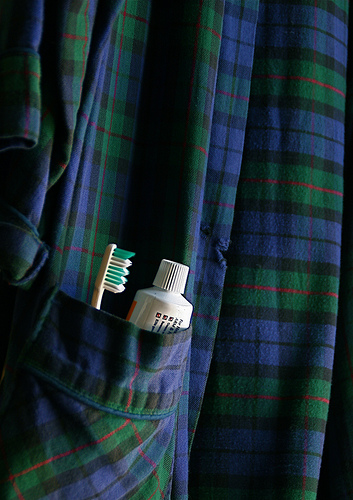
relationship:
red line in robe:
[238, 168, 343, 202] [2, 4, 347, 494]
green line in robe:
[252, 80, 339, 111] [2, 4, 347, 494]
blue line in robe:
[233, 217, 343, 265] [2, 4, 347, 494]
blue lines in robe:
[146, 421, 334, 479] [2, 4, 347, 494]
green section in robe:
[104, 139, 136, 162] [2, 4, 347, 494]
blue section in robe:
[236, 43, 255, 70] [2, 4, 347, 494]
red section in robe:
[239, 174, 275, 186] [2, 4, 347, 494]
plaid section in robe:
[14, 342, 193, 496] [2, 4, 347, 494]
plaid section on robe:
[14, 342, 193, 496] [2, 4, 347, 494]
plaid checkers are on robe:
[6, 1, 332, 267] [2, 4, 347, 494]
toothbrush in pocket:
[86, 239, 134, 317] [32, 299, 195, 492]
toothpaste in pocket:
[130, 255, 199, 331] [32, 299, 195, 492]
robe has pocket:
[2, 4, 347, 494] [32, 299, 195, 492]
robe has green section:
[2, 4, 347, 494] [104, 139, 136, 162]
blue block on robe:
[318, 32, 343, 65] [2, 4, 347, 494]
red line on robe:
[238, 168, 343, 202] [2, 4, 347, 494]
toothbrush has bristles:
[86, 239, 134, 317] [112, 244, 134, 297]